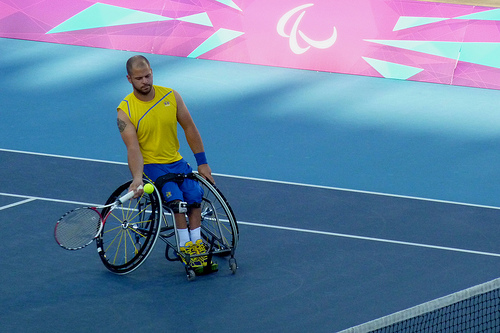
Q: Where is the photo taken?
A: Tennis court.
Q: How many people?
A: One.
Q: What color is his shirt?
A: Yellow.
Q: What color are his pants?
A: Blue.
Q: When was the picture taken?
A: Day time.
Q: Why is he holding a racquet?
A: Playing.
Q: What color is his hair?
A: Brown.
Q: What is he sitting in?
A: Wheelchair.